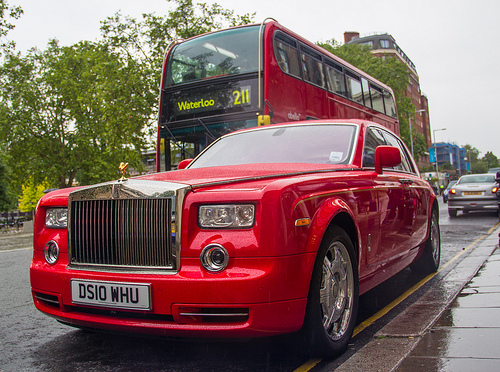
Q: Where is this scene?
A: Street side.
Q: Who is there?
A: No one.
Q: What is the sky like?
A: Overcast.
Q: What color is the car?
A: Red.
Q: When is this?
A: Afternoon.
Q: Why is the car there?
A: Parked.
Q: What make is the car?
A: Bentley.